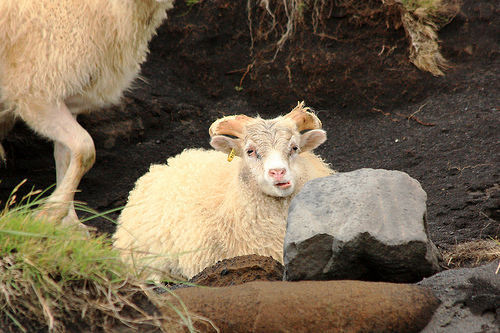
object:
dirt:
[3, 1, 498, 242]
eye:
[246, 148, 255, 156]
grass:
[0, 178, 220, 331]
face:
[244, 124, 296, 190]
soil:
[85, 70, 493, 257]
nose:
[269, 168, 285, 177]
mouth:
[272, 179, 292, 189]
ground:
[3, 5, 498, 280]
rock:
[281, 167, 441, 281]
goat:
[111, 102, 338, 283]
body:
[128, 149, 268, 260]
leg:
[27, 93, 97, 226]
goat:
[4, 0, 173, 230]